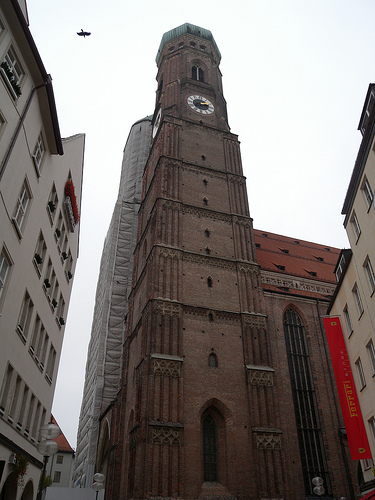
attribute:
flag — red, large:
[313, 304, 374, 468]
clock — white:
[185, 89, 217, 121]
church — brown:
[98, 6, 288, 492]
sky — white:
[224, 8, 360, 166]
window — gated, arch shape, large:
[272, 293, 322, 500]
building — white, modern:
[0, 122, 90, 490]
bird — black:
[70, 23, 99, 48]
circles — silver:
[138, 83, 232, 144]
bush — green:
[6, 450, 39, 482]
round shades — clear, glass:
[304, 469, 333, 499]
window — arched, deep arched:
[189, 381, 240, 495]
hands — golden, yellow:
[195, 96, 210, 110]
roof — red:
[254, 225, 335, 279]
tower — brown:
[134, 12, 261, 297]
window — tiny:
[194, 150, 211, 165]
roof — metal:
[148, 17, 228, 78]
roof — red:
[260, 229, 335, 286]